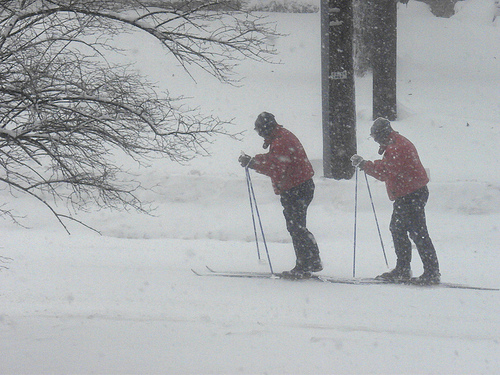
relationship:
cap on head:
[256, 111, 279, 135] [252, 109, 279, 141]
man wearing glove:
[217, 91, 327, 282] [348, 155, 363, 170]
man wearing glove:
[350, 115, 441, 285] [235, 153, 251, 168]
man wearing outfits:
[350, 115, 441, 285] [239, 127, 339, 278]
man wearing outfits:
[217, 91, 327, 282] [352, 132, 442, 288]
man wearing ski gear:
[217, 91, 327, 282] [240, 111, 320, 276]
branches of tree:
[1, 3, 288, 233] [0, 1, 300, 232]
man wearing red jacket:
[350, 115, 441, 285] [363, 130, 429, 200]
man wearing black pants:
[350, 115, 441, 285] [389, 184, 440, 279]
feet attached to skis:
[377, 263, 453, 289] [326, 271, 498, 298]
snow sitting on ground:
[41, 253, 202, 355] [21, 260, 497, 365]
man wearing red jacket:
[217, 91, 327, 282] [243, 122, 316, 194]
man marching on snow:
[350, 115, 441, 285] [0, 0, 500, 374]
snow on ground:
[132, 282, 408, 373] [80, 300, 417, 373]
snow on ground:
[0, 0, 500, 374] [6, 13, 492, 371]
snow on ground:
[301, 286, 407, 331] [445, 233, 497, 266]